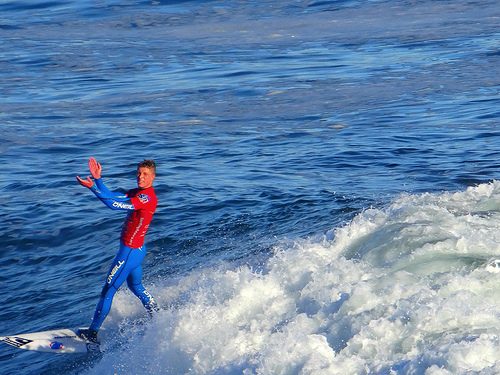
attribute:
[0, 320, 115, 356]
surfboard — white 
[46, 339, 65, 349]
sticker — black , white 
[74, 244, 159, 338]
pants — blue 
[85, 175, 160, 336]
wetsuit — red, blue 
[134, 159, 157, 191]
hair — brown , short 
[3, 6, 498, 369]
water — clear , blue 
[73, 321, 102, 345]
shoe — black 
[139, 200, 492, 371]
waves — white 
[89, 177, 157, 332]
wet suit — blue 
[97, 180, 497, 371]
wave — white 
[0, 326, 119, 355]
surfboard — white 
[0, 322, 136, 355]
white surfboard — white 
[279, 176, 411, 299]
white water — white 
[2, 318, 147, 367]
surfboard — white 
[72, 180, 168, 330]
wetsuit — blue , red 